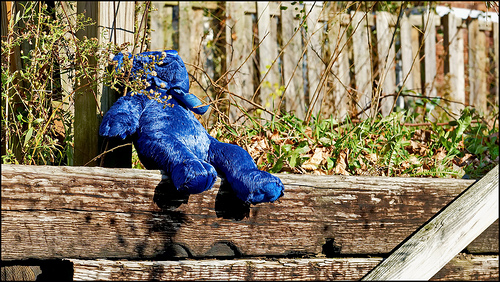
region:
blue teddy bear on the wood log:
[102, 49, 274, 205]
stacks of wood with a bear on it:
[0, 164, 497, 279]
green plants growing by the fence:
[0, 0, 498, 178]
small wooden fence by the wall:
[0, 4, 497, 139]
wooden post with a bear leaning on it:
[71, 0, 135, 170]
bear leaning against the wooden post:
[100, 46, 287, 206]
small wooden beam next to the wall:
[358, 166, 496, 281]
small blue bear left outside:
[99, 46, 284, 204]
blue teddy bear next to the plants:
[103, 52, 284, 202]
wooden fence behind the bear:
[1, 1, 497, 140]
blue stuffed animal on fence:
[96, 39, 291, 206]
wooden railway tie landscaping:
[6, 150, 493, 268]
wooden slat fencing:
[178, 3, 495, 120]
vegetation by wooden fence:
[238, 83, 499, 170]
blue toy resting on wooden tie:
[107, 50, 400, 248]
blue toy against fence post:
[73, 3, 283, 207]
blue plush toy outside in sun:
[96, 45, 288, 213]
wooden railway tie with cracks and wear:
[4, 177, 390, 258]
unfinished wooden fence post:
[67, 4, 134, 167]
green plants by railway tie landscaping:
[233, 110, 495, 258]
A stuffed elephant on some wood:
[122, 63, 272, 195]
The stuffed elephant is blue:
[109, 47, 273, 207]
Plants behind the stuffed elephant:
[301, 125, 463, 167]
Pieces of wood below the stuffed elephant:
[8, 168, 493, 272]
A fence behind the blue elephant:
[247, 10, 479, 100]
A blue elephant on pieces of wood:
[3, 44, 498, 278]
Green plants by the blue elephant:
[8, 13, 74, 157]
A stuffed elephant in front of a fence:
[109, 55, 281, 205]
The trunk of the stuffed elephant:
[168, 85, 210, 110]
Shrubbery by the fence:
[271, 129, 456, 165]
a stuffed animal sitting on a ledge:
[69, 12, 294, 231]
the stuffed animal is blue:
[86, 25, 298, 220]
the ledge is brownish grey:
[22, 141, 352, 256]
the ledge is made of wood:
[5, 146, 347, 271]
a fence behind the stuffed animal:
[53, 0, 445, 137]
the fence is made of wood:
[80, 0, 427, 140]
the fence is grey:
[191, 2, 446, 133]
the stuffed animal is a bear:
[50, 26, 300, 221]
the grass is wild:
[250, 67, 465, 177]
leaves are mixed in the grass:
[275, 117, 453, 178]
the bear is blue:
[110, 23, 306, 251]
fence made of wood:
[95, 2, 475, 139]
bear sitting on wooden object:
[95, 15, 295, 206]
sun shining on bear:
[121, 26, 308, 251]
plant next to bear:
[6, 15, 121, 155]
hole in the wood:
[305, 225, 345, 251]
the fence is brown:
[185, 5, 431, 117]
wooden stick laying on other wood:
[373, 135, 497, 277]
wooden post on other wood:
[72, 4, 159, 169]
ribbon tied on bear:
[159, 81, 216, 123]